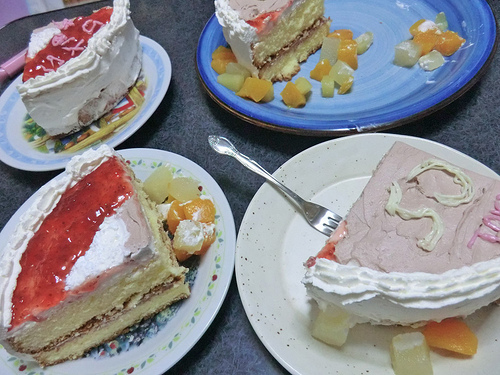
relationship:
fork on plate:
[216, 128, 346, 240] [261, 138, 383, 304]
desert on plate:
[224, 9, 397, 101] [220, 25, 408, 108]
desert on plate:
[224, 9, 397, 101] [68, 145, 196, 340]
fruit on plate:
[225, 54, 425, 125] [220, 25, 408, 108]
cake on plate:
[57, 156, 205, 294] [68, 145, 196, 340]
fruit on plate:
[225, 54, 425, 125] [68, 145, 196, 340]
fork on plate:
[216, 128, 346, 240] [220, 25, 408, 108]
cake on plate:
[0, 143, 192, 366] [68, 145, 196, 340]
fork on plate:
[216, 128, 346, 240] [236, 128, 499, 372]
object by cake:
[0, 46, 25, 70] [57, 156, 205, 294]